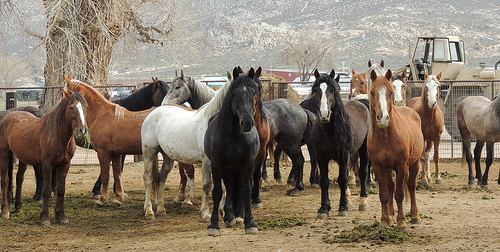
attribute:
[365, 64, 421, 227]
horse — brown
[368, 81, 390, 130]
striped nose — white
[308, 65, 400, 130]
faces — white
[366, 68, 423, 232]
horse — brown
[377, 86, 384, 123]
whitemark — white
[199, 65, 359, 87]
buildings — red and white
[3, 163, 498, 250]
ground — brown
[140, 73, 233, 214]
horse — white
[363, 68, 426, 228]
horse — standing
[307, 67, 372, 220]
horse — standing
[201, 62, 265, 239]
horse — black, standing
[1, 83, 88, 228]
horse — standing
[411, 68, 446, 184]
horse — standing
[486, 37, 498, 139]
machinery — heavy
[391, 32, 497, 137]
tractor — tan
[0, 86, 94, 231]
horse — Brown 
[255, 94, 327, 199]
horse — black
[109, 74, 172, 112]
horse — black